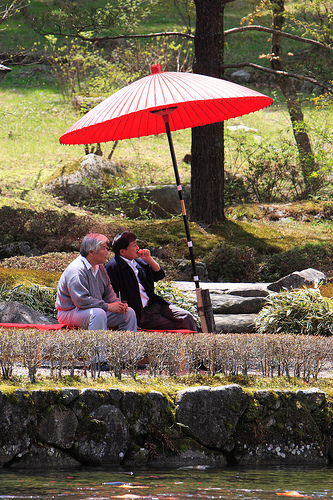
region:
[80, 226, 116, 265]
head of a person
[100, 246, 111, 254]
nose of a person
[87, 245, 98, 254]
ear of a person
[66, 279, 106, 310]
arm of a person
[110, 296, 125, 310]
hand of a person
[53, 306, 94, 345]
thigh of a person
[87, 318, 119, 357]
leg of a person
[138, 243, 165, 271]
arm of a person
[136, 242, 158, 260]
hand of a person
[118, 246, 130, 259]
ear of a person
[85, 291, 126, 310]
arm of a person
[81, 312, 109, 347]
leg of a person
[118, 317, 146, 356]
leg of a person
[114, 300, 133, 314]
hand of a person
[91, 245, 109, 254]
eye of a person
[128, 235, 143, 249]
eye of a person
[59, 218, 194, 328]
men under the parasol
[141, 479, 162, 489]
water in the river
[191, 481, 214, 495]
water in the river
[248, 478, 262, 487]
water in the river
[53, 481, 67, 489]
water in the river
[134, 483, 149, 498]
water in the river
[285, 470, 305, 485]
water in the river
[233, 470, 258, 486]
water in the river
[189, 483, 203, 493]
water in the river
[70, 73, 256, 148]
red umbrella near water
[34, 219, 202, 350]
two men under umbrella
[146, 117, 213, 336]
black pole with umbrella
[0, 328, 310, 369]
small bushes near men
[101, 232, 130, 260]
man has black hair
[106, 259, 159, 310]
man has white shirt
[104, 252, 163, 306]
man has blue coat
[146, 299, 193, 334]
man has grey pants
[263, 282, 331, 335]
green bush near men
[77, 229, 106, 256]
man has grey hair